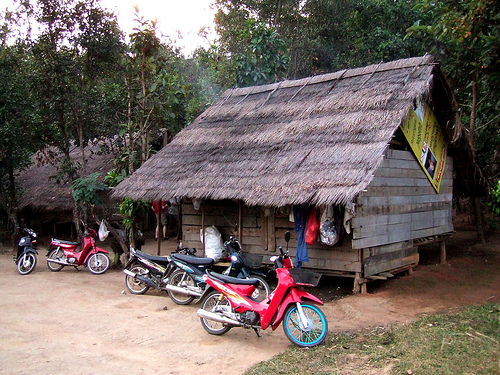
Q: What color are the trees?
A: Green.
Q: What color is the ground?
A: Tan.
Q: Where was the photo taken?
A: Countryside.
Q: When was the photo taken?
A: Daytime.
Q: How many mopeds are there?
A: Five.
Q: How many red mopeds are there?
A: Two.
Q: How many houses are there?
A: One.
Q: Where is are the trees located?
A: Behind the house.